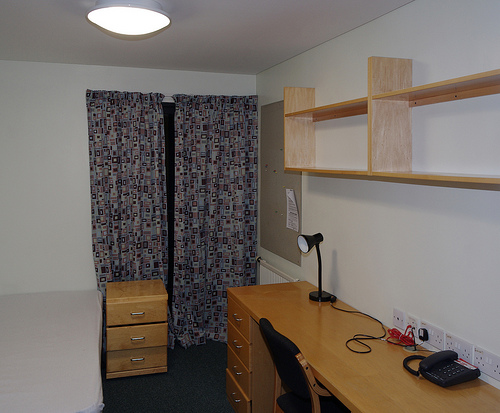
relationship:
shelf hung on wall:
[285, 94, 367, 117] [257, 0, 498, 390]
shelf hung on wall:
[372, 68, 500, 101] [257, 0, 498, 390]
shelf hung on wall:
[284, 166, 368, 178] [257, 0, 498, 390]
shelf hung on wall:
[369, 170, 499, 186] [257, 0, 498, 390]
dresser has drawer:
[104, 279, 170, 380] [106, 298, 169, 326]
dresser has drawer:
[104, 279, 170, 380] [106, 322, 169, 352]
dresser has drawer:
[104, 279, 170, 380] [106, 346, 169, 374]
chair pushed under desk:
[257, 317, 350, 413] [225, 280, 500, 413]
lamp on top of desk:
[296, 232, 332, 302] [225, 280, 500, 413]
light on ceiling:
[86, 6, 172, 36] [2, 1, 415, 74]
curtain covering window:
[172, 93, 259, 348] [162, 102, 175, 311]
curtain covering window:
[85, 89, 174, 349] [162, 102, 175, 311]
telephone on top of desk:
[404, 350, 482, 387] [225, 280, 500, 413]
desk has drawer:
[225, 280, 500, 413] [226, 292, 254, 345]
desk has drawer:
[225, 280, 500, 413] [227, 318, 253, 374]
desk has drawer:
[225, 280, 500, 413] [226, 344, 254, 402]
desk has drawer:
[225, 280, 500, 413] [224, 368, 251, 412]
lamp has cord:
[296, 232, 332, 302] [329, 299, 430, 354]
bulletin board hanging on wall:
[258, 99, 303, 268] [257, 0, 498, 390]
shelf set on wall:
[282, 56, 499, 190] [257, 0, 498, 390]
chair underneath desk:
[257, 317, 350, 413] [225, 280, 500, 413]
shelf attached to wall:
[285, 94, 367, 117] [257, 0, 498, 390]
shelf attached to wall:
[372, 68, 500, 101] [257, 0, 498, 390]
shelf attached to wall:
[284, 166, 368, 178] [257, 0, 498, 390]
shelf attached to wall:
[369, 170, 499, 186] [257, 0, 498, 390]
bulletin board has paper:
[258, 99, 303, 268] [284, 187, 302, 233]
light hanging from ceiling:
[86, 6, 172, 36] [2, 1, 415, 74]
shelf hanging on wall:
[285, 94, 367, 117] [257, 0, 498, 390]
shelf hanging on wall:
[372, 68, 500, 101] [257, 0, 498, 390]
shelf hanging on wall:
[284, 166, 368, 178] [257, 0, 498, 390]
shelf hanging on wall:
[369, 170, 499, 186] [257, 0, 498, 390]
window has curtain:
[162, 102, 175, 311] [172, 93, 259, 348]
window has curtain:
[162, 102, 175, 311] [85, 89, 174, 349]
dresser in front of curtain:
[104, 279, 170, 380] [85, 89, 174, 349]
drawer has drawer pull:
[106, 298, 169, 326] [131, 311, 143, 316]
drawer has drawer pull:
[106, 322, 169, 352] [131, 336, 145, 342]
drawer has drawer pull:
[106, 346, 169, 374] [130, 357, 143, 362]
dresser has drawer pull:
[104, 279, 170, 380] [131, 311, 143, 316]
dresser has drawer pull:
[104, 279, 170, 380] [131, 336, 145, 342]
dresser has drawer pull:
[104, 279, 170, 380] [130, 357, 143, 362]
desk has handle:
[225, 280, 500, 413] [232, 311, 244, 322]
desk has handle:
[225, 280, 500, 413] [231, 337, 242, 350]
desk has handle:
[225, 280, 500, 413] [231, 363, 245, 377]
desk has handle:
[225, 280, 500, 413] [229, 390, 243, 405]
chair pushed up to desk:
[257, 317, 350, 413] [225, 280, 500, 413]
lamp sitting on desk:
[296, 232, 332, 302] [225, 280, 500, 413]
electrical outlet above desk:
[473, 346, 500, 379] [225, 280, 500, 413]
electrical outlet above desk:
[443, 332, 471, 365] [225, 280, 500, 413]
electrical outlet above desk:
[418, 318, 444, 353] [225, 280, 500, 413]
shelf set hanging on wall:
[282, 56, 499, 190] [257, 0, 498, 390]